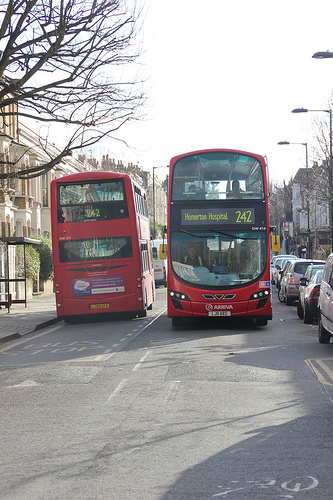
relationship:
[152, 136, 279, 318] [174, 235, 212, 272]
bus with male driver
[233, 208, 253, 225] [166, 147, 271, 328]
242 on front of bus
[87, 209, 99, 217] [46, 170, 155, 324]
242 on front of bus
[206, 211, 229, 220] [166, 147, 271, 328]
yellow word on front of bus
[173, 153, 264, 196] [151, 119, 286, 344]
window of bus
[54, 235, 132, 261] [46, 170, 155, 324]
bottom window of bus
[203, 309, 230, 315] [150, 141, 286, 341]
license plate on bus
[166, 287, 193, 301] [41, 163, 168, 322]
lights on bus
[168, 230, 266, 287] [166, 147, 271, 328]
windshield on bus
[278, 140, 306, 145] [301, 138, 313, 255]
street lamp on pole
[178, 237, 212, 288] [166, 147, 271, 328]
driver of bus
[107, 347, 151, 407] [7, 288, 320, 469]
lines painted on road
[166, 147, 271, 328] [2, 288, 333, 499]
bus on road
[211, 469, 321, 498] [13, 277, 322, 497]
mark on pavement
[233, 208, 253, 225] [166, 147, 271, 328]
242 on bus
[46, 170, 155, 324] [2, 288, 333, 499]
bus going down road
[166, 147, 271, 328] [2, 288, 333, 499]
bus going down road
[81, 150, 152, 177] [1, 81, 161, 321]
chimneys on building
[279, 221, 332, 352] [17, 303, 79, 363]
cars parkerd curb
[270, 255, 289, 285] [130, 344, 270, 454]
car parked street